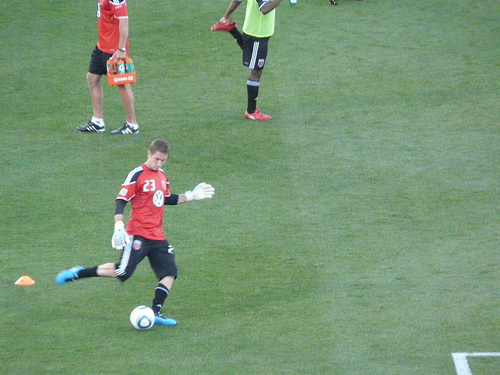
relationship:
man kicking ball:
[54, 132, 216, 330] [108, 299, 197, 337]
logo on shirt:
[155, 190, 164, 210] [117, 166, 172, 241]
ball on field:
[128, 301, 158, 339] [169, 299, 279, 349]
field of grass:
[3, 2, 497, 372] [0, 2, 498, 372]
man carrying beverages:
[54, 139, 215, 327] [104, 43, 148, 91]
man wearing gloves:
[54, 132, 216, 330] [188, 175, 218, 205]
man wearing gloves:
[54, 132, 216, 330] [106, 220, 136, 252]